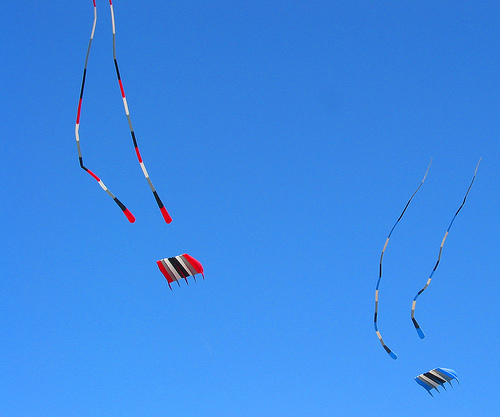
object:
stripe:
[182, 252, 206, 274]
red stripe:
[153, 205, 179, 226]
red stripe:
[119, 202, 138, 226]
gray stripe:
[105, 187, 116, 199]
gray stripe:
[142, 176, 160, 193]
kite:
[66, 0, 211, 294]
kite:
[367, 148, 488, 400]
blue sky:
[0, 0, 500, 417]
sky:
[0, 0, 495, 417]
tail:
[371, 153, 488, 363]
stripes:
[432, 366, 462, 383]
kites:
[358, 149, 484, 403]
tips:
[412, 145, 494, 185]